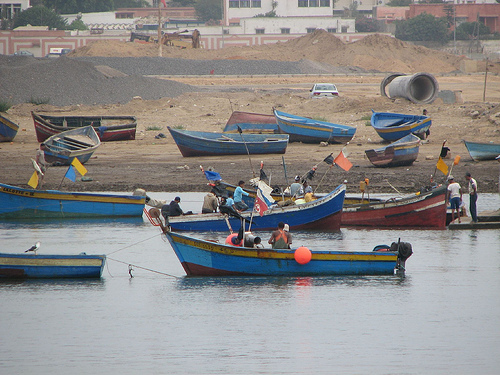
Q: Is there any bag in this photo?
A: No, there are no bags.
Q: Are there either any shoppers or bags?
A: No, there are no bags or shoppers.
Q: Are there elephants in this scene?
A: No, there are no elephants.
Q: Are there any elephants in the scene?
A: No, there are no elephants.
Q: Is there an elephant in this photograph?
A: No, there are no elephants.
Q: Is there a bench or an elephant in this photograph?
A: No, there are no elephants or benches.